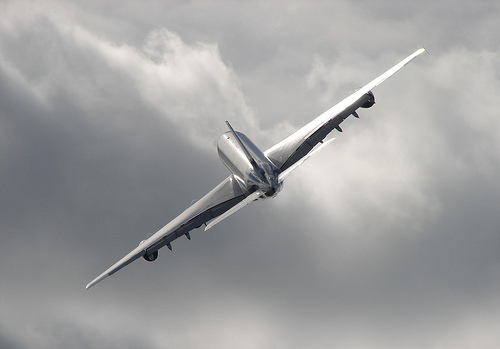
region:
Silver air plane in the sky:
[91, 47, 430, 294]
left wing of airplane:
[86, 172, 235, 290]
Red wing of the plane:
[280, 44, 429, 164]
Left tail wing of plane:
[203, 190, 255, 234]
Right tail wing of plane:
[279, 126, 342, 183]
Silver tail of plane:
[222, 108, 260, 172]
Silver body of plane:
[213, 125, 271, 196]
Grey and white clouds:
[2, 2, 495, 346]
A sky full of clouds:
[3, 1, 495, 347]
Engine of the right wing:
[355, 85, 375, 111]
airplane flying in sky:
[66, 31, 431, 301]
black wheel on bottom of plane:
[136, 248, 172, 270]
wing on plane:
[71, 168, 243, 310]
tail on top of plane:
[223, 113, 270, 183]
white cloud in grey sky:
[119, 25, 268, 119]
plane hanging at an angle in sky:
[55, 38, 438, 308]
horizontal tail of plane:
[197, 131, 348, 231]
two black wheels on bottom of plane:
[130, 85, 379, 271]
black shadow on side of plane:
[212, 141, 248, 189]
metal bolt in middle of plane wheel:
[146, 245, 159, 262]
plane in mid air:
[70, 40, 446, 317]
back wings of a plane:
[207, 125, 341, 232]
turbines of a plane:
[139, 245, 168, 263]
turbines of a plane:
[345, 85, 388, 115]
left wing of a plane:
[68, 154, 232, 299]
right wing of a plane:
[255, 28, 428, 190]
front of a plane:
[209, 123, 244, 148]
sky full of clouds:
[35, 25, 207, 138]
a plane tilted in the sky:
[49, 18, 470, 310]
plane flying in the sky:
[55, 28, 472, 328]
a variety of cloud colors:
[70, 85, 476, 318]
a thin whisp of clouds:
[138, 24, 177, 69]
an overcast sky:
[31, 17, 443, 311]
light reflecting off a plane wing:
[267, 58, 412, 148]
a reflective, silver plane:
[86, 43, 430, 290]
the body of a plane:
[211, 127, 281, 201]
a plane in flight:
[83, 45, 427, 290]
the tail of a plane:
[206, 120, 341, 231]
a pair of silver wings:
[84, 45, 430, 282]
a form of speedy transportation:
[74, 30, 430, 290]